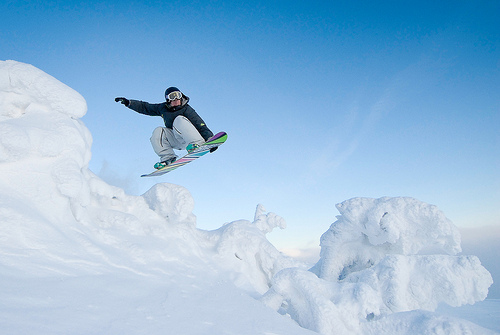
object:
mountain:
[2, 61, 493, 334]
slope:
[2, 59, 325, 334]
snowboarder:
[137, 132, 227, 179]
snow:
[0, 270, 205, 335]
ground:
[281, 196, 498, 334]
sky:
[1, 1, 499, 242]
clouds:
[313, 86, 387, 180]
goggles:
[165, 92, 182, 103]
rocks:
[320, 196, 492, 312]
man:
[115, 87, 219, 170]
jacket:
[127, 93, 217, 142]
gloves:
[115, 97, 127, 104]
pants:
[151, 116, 206, 162]